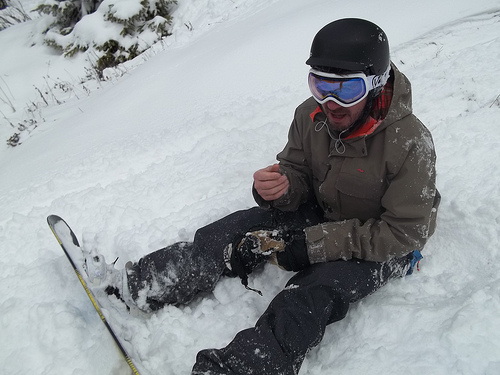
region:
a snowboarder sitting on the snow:
[29, 12, 464, 367]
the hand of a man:
[240, 160, 295, 205]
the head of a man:
[289, 12, 405, 138]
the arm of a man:
[259, 224, 396, 266]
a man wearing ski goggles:
[298, 9, 403, 129]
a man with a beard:
[297, 11, 394, 131]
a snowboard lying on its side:
[19, 203, 163, 372]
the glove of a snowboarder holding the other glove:
[221, 220, 307, 290]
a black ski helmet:
[301, 8, 399, 73]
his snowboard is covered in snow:
[20, 186, 210, 369]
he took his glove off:
[192, 135, 337, 282]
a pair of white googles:
[291, 49, 403, 103]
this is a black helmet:
[278, 8, 411, 78]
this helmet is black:
[290, 10, 408, 80]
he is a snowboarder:
[12, 0, 496, 370]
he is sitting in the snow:
[5, 5, 467, 363]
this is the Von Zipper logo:
[365, 68, 398, 91]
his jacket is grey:
[247, 15, 476, 283]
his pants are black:
[117, 178, 419, 373]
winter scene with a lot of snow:
[6, 4, 493, 366]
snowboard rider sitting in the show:
[45, 15, 437, 365]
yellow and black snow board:
[45, 212, 155, 367]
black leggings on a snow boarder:
[125, 190, 421, 370]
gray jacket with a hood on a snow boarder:
[251, 61, 436, 266]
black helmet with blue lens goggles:
[302, 10, 387, 100]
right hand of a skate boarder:
[250, 160, 287, 200]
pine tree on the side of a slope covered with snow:
[21, 0, 183, 75]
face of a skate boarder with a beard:
[305, 65, 375, 135]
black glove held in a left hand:
[217, 227, 263, 298]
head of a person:
[280, 21, 410, 132]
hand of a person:
[225, 148, 302, 209]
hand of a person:
[267, 219, 331, 274]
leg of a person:
[133, 175, 310, 303]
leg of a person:
[245, 233, 413, 355]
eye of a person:
[302, 48, 386, 110]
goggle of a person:
[310, 65, 380, 103]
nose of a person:
[316, 85, 360, 112]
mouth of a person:
[309, 103, 371, 127]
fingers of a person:
[255, 155, 296, 210]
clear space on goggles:
[311, 80, 360, 96]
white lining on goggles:
[365, 76, 372, 91]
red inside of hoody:
[365, 120, 372, 130]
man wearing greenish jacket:
[397, 155, 409, 179]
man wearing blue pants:
[311, 290, 326, 312]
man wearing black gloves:
[288, 233, 302, 268]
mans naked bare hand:
[260, 168, 282, 202]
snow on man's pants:
[148, 274, 169, 302]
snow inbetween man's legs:
[200, 315, 227, 335]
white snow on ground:
[430, 280, 469, 327]